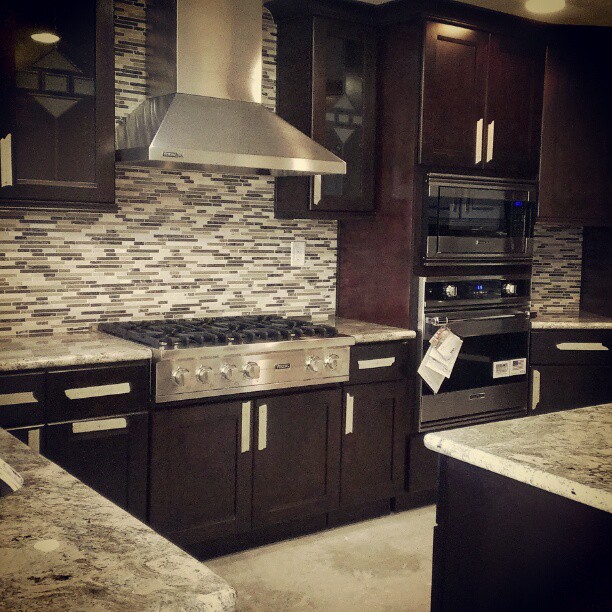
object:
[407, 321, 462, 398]
discloths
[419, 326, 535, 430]
oven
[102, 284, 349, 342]
burners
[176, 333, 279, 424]
stove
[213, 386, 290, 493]
cabinet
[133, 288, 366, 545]
kitchen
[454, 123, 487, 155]
cabinet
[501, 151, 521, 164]
cabinet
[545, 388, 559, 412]
cabinet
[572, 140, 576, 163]
cabinet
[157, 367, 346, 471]
stove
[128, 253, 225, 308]
skinny tiles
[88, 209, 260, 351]
backsplash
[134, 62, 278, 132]
vent hood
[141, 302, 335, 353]
cooktop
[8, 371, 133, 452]
tape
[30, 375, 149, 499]
drawers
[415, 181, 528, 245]
built-in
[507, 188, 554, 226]
oven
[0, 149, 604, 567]
kitchen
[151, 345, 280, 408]
knobs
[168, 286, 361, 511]
stove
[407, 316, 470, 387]
papers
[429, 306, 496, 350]
door